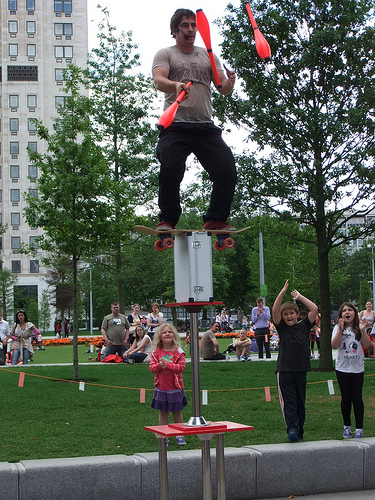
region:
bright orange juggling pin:
[149, 71, 193, 132]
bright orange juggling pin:
[192, 3, 233, 91]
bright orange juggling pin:
[241, 0, 282, 64]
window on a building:
[25, 116, 41, 136]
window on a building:
[6, 186, 19, 211]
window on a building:
[6, 231, 23, 256]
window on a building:
[28, 234, 40, 251]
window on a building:
[27, 161, 36, 181]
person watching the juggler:
[146, 317, 191, 446]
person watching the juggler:
[258, 274, 332, 441]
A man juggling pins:
[146, 0, 274, 233]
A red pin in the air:
[237, 2, 276, 64]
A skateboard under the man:
[131, 222, 249, 248]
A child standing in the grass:
[148, 321, 190, 450]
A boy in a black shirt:
[267, 278, 320, 440]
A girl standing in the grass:
[328, 302, 370, 438]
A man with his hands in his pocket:
[99, 301, 131, 359]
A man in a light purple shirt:
[248, 296, 274, 357]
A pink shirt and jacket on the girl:
[148, 345, 188, 390]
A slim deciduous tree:
[27, 59, 133, 386]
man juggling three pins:
[144, 7, 267, 248]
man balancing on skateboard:
[145, 3, 255, 240]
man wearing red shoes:
[147, 7, 249, 231]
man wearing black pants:
[151, 11, 238, 230]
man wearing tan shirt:
[148, 8, 241, 231]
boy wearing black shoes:
[269, 285, 316, 440]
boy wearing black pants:
[267, 280, 319, 443]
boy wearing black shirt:
[268, 282, 318, 447]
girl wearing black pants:
[329, 303, 368, 441]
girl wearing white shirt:
[327, 302, 372, 438]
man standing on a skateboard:
[136, 3, 247, 245]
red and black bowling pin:
[238, 1, 277, 69]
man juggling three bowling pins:
[155, 2, 279, 133]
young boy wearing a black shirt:
[272, 272, 316, 440]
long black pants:
[273, 362, 313, 448]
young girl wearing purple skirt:
[147, 317, 190, 446]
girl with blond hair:
[143, 314, 184, 356]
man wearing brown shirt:
[99, 299, 135, 356]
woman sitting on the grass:
[125, 322, 152, 370]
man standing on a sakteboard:
[134, 7, 264, 254]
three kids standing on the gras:
[139, 278, 370, 437]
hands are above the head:
[265, 274, 324, 327]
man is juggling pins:
[134, 1, 304, 153]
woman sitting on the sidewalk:
[121, 325, 155, 366]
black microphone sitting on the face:
[176, 27, 193, 43]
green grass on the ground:
[0, 352, 374, 461]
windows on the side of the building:
[6, 90, 48, 275]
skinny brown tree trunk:
[64, 261, 91, 382]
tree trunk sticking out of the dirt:
[58, 360, 97, 386]